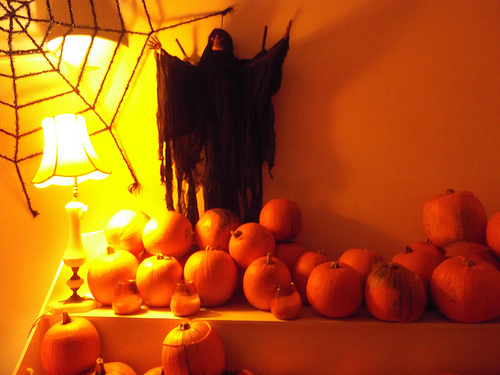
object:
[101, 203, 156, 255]
pumpkin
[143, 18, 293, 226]
cloak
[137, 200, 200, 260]
pumpkin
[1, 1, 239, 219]
web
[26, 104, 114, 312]
lamp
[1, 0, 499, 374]
wall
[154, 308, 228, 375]
pumpkin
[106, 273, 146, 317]
candle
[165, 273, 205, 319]
candle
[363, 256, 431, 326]
pumkin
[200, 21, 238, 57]
head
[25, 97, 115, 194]
shade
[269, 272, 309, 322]
candle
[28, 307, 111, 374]
pumpkin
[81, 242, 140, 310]
pumpkin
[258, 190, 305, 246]
pumpkin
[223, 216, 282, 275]
pumpkin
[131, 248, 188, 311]
pumpkin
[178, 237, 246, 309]
pumpkin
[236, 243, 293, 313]
pumpkin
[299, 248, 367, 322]
pumpkin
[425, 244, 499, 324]
pumpkin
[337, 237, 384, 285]
pumpkin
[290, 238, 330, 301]
pumpkin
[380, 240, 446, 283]
pumpkin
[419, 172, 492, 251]
pumpkin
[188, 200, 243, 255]
pumpkin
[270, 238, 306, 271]
pumpkin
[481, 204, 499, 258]
pumpkin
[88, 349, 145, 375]
pumpkin